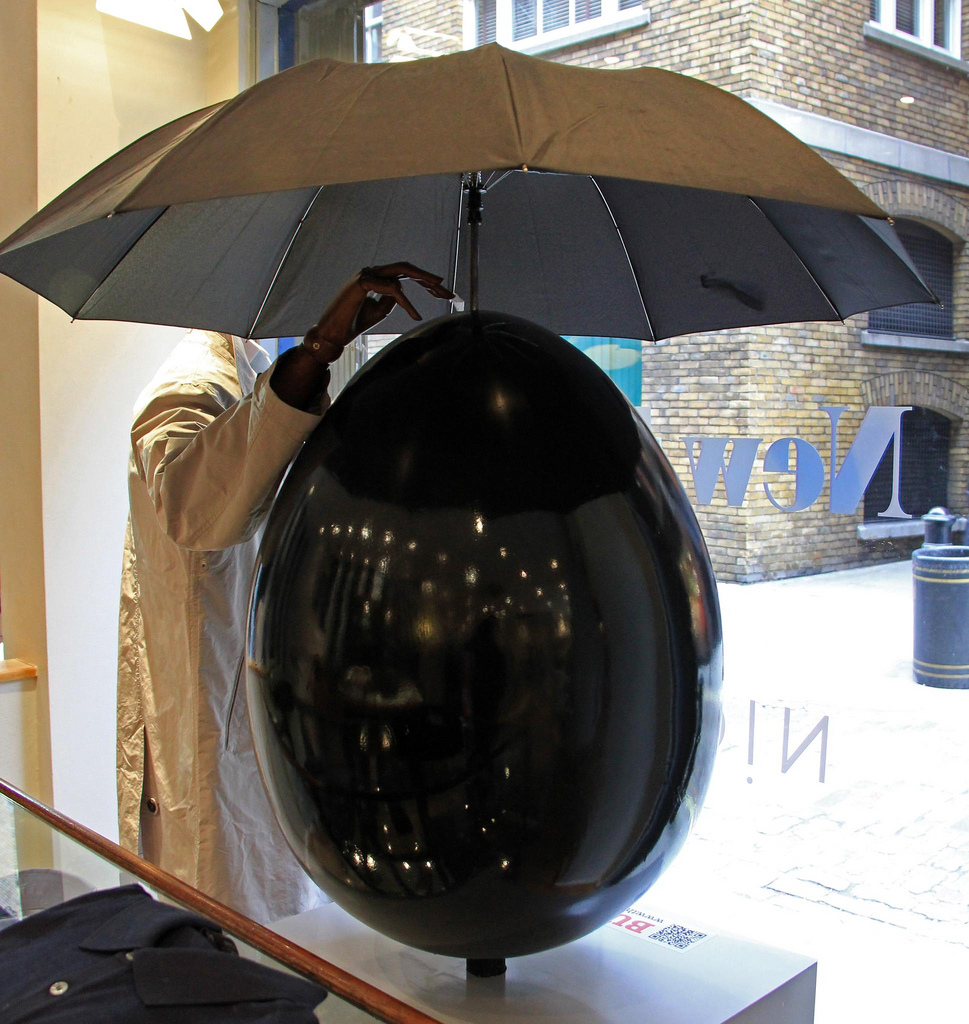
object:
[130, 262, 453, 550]
arm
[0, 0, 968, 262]
air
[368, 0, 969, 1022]
outside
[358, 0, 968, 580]
building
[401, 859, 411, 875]
light glare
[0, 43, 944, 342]
umbrella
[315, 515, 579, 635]
lights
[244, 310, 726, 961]
egg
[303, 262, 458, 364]
hand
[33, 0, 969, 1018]
window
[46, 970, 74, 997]
button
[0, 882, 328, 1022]
shirt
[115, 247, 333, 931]
overcoat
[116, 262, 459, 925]
mannequin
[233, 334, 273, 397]
collar